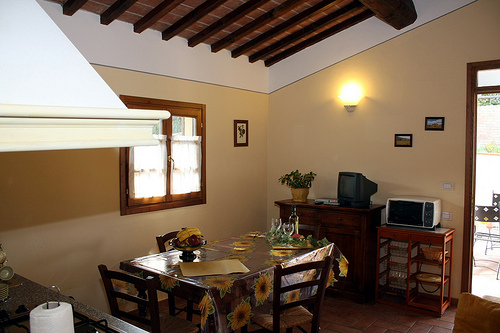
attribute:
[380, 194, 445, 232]
microwave — oven, white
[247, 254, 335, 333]
chair — brown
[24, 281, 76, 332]
towel roll — white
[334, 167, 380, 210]
tv — old, black, small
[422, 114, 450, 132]
picture — small, framed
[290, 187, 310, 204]
vase — yellow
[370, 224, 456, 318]
stand — small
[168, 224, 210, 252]
fruit — arranged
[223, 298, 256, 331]
daisy — yellow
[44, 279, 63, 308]
holder — silver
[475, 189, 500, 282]
chairs — outdoor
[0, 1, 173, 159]
vent — white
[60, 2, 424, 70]
beams — dark